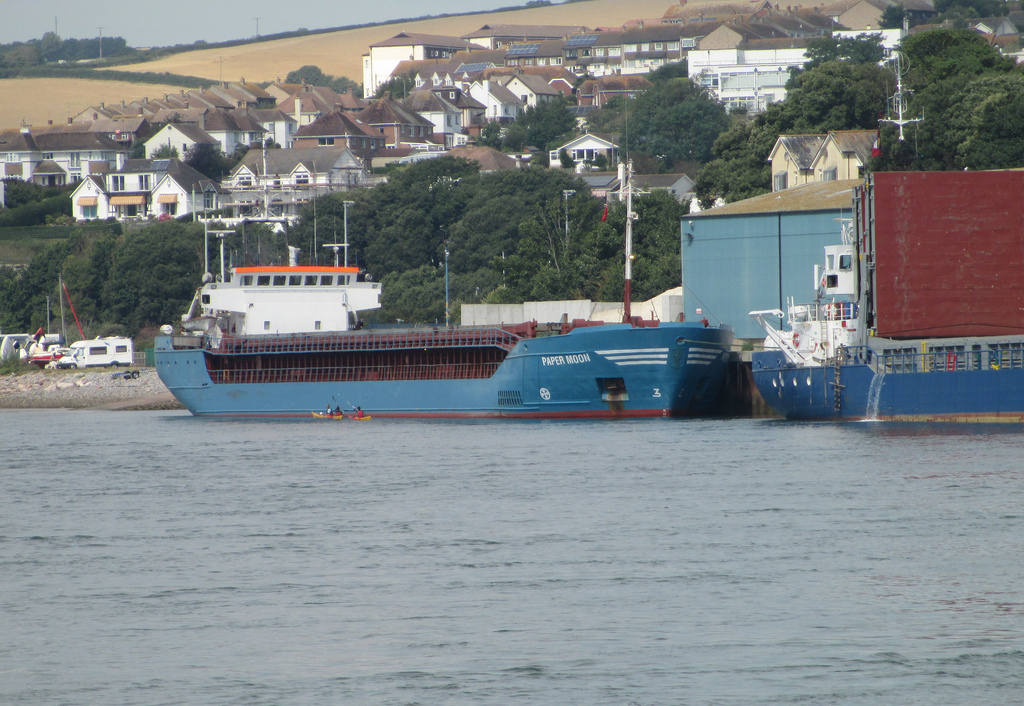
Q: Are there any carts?
A: No, there are no carts.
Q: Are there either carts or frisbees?
A: No, there are no carts or frisbees.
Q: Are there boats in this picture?
A: Yes, there is a boat.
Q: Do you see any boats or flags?
A: Yes, there is a boat.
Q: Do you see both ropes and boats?
A: No, there is a boat but no ropes.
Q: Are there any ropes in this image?
A: No, there are no ropes.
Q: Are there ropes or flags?
A: No, there are no ropes or flags.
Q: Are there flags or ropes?
A: No, there are no ropes or flags.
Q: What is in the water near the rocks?
A: The boat is in the water.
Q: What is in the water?
A: The boat is in the water.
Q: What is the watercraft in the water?
A: The watercraft is a boat.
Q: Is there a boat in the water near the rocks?
A: Yes, there is a boat in the water.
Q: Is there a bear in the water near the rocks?
A: No, there is a boat in the water.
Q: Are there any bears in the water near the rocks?
A: No, there is a boat in the water.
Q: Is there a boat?
A: Yes, there is a boat.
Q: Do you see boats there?
A: Yes, there is a boat.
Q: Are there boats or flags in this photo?
A: Yes, there is a boat.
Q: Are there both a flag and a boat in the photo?
A: No, there is a boat but no flags.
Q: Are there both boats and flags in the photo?
A: No, there is a boat but no flags.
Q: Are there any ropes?
A: No, there are no ropes.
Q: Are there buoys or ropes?
A: No, there are no ropes or buoys.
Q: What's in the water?
A: The boat is in the water.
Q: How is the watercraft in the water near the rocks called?
A: The watercraft is a boat.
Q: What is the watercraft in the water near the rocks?
A: The watercraft is a boat.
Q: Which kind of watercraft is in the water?
A: The watercraft is a boat.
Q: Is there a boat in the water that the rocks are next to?
A: Yes, there is a boat in the water.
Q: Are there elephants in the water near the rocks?
A: No, there is a boat in the water.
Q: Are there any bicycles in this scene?
A: No, there are no bicycles.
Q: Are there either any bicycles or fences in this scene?
A: No, there are no bicycles or fences.